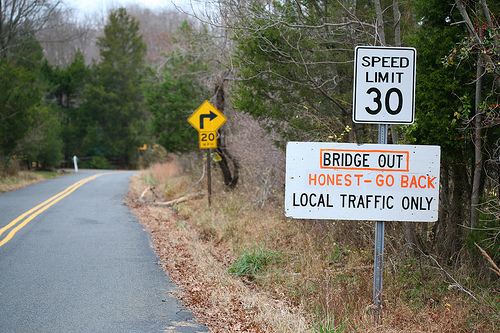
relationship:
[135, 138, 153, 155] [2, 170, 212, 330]
sign in road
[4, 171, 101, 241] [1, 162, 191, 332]
line in road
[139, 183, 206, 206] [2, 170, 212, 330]
log in road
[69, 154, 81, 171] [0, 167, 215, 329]
mail box in road side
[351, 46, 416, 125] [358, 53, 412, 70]
road sign with black writing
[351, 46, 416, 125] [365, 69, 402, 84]
road sign with black writing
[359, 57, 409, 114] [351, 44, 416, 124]
writting on road sign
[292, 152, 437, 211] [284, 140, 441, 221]
writting on road sign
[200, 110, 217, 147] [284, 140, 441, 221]
writting on road sign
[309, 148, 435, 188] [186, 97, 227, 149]
writting on road sign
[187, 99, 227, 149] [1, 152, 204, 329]
road sign on road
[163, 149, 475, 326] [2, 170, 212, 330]
bushes on road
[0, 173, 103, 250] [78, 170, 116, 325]
line on road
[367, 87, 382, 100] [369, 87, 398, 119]
part of number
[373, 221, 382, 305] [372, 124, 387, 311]
part of pole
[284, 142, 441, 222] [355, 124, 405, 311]
road sign on pole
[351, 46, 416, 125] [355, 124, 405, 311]
road sign on pole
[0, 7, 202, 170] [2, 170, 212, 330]
pin tree on road